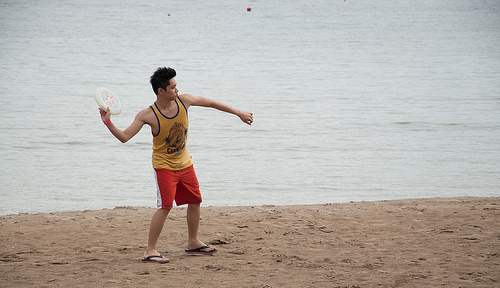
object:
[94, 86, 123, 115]
frisbee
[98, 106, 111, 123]
right hand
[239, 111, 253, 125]
hand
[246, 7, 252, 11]
red buoy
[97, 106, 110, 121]
hand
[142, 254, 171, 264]
sandal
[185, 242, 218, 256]
sandal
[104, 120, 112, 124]
band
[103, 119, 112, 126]
wrist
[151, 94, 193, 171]
design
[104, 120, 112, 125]
bracelet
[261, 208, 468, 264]
shore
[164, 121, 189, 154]
picture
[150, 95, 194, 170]
shirt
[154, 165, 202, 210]
shorts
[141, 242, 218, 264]
shoes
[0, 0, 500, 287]
picture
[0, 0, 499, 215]
waters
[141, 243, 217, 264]
flip flops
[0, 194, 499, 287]
dirt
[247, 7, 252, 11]
ball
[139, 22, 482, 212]
water field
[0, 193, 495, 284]
sand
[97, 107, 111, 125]
man`s hand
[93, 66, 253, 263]
man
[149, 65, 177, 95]
hair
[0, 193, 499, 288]
footprints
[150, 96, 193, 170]
tank top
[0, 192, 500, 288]
beach